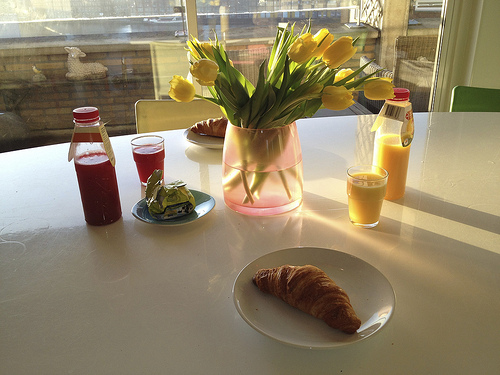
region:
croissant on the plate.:
[294, 273, 314, 283]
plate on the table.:
[277, 317, 317, 352]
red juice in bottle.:
[92, 170, 107, 207]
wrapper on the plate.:
[164, 183, 187, 211]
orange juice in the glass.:
[357, 196, 376, 213]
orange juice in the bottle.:
[387, 149, 403, 185]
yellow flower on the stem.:
[320, 41, 344, 57]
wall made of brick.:
[112, 70, 127, 87]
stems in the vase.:
[245, 90, 275, 114]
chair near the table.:
[465, 92, 494, 103]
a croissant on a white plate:
[237, 249, 409, 349]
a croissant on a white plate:
[185, 117, 225, 151]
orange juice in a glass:
[340, 163, 392, 230]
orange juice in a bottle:
[374, 87, 414, 204]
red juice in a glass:
[124, 132, 174, 184]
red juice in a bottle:
[64, 104, 126, 236]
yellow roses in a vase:
[163, 14, 397, 219]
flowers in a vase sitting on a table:
[207, 31, 339, 218]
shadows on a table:
[409, 187, 499, 275]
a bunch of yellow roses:
[162, 15, 394, 132]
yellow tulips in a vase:
[164, 13, 396, 217]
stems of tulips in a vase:
[221, 129, 302, 217]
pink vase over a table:
[212, 122, 310, 223]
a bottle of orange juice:
[362, 71, 417, 208]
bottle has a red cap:
[365, 81, 415, 206]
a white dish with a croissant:
[222, 242, 404, 362]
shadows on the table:
[420, 192, 498, 283]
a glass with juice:
[125, 123, 173, 184]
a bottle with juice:
[61, 98, 131, 238]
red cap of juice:
[62, 98, 129, 239]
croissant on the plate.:
[293, 271, 334, 293]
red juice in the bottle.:
[91, 165, 104, 225]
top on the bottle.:
[72, 103, 95, 120]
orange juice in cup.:
[353, 193, 383, 213]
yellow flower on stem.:
[297, 40, 313, 62]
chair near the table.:
[152, 107, 178, 117]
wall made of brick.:
[62, 91, 118, 98]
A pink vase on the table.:
[215, 107, 311, 224]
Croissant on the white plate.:
[265, 272, 351, 332]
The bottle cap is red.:
[384, 87, 415, 105]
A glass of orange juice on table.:
[343, 158, 393, 226]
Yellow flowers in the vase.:
[209, 40, 360, 107]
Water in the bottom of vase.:
[230, 165, 297, 202]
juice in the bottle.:
[59, 100, 115, 253]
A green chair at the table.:
[451, 76, 489, 115]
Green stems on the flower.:
[233, 67, 290, 122]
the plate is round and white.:
[236, 236, 398, 343]